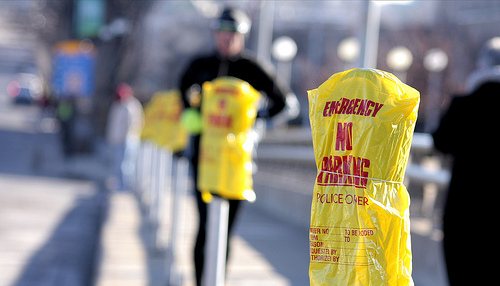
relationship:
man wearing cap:
[99, 82, 141, 192] [117, 84, 131, 101]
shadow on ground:
[19, 180, 110, 284] [0, 131, 440, 284]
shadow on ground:
[228, 200, 314, 283] [0, 131, 440, 284]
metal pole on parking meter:
[201, 197, 233, 284] [202, 77, 259, 197]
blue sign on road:
[50, 52, 97, 98] [2, 73, 104, 284]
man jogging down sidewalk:
[176, 7, 288, 286] [56, 126, 311, 282]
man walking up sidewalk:
[430, 69, 499, 286] [106, 136, 498, 284]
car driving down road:
[6, 74, 43, 101] [4, 91, 76, 280]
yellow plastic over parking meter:
[302, 64, 425, 284] [303, 62, 423, 284]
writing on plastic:
[312, 97, 393, 208] [304, 66, 424, 285]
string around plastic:
[312, 166, 408, 186] [304, 66, 424, 285]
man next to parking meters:
[176, 7, 288, 286] [197, 77, 259, 284]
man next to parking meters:
[176, 7, 288, 286] [303, 66, 420, 284]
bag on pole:
[191, 78, 263, 207] [204, 192, 231, 282]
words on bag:
[317, 97, 384, 191] [296, 61, 425, 283]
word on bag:
[315, 94, 385, 191] [296, 61, 425, 283]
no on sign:
[333, 115, 360, 155] [289, 61, 425, 283]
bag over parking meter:
[305, 67, 421, 286] [328, 70, 388, 103]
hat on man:
[201, 0, 253, 31] [170, 6, 305, 284]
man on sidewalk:
[170, 6, 305, 284] [96, 167, 309, 284]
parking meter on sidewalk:
[287, 62, 418, 284] [96, 167, 309, 284]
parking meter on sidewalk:
[197, 75, 271, 283] [96, 167, 309, 284]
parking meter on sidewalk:
[142, 80, 197, 262] [96, 167, 309, 284]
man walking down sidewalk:
[430, 69, 499, 286] [138, 128, 365, 284]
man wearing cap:
[105, 82, 145, 189] [116, 82, 134, 99]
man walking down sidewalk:
[105, 82, 145, 189] [49, 180, 194, 276]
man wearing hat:
[176, 6, 295, 281] [213, 4, 253, 34]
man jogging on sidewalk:
[176, 6, 295, 281] [0, 178, 282, 284]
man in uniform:
[176, 7, 288, 286] [174, 47, 299, 283]